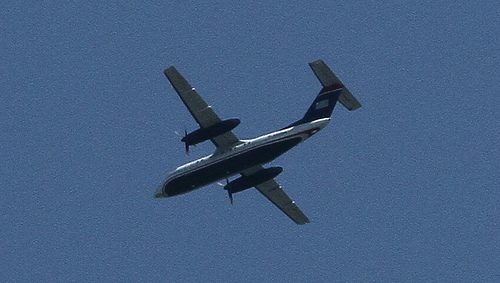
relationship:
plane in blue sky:
[150, 58, 363, 226] [2, 2, 499, 280]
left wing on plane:
[161, 65, 241, 149] [150, 58, 363, 226]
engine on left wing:
[176, 112, 242, 153] [161, 65, 241, 149]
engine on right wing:
[219, 164, 289, 204] [240, 163, 316, 224]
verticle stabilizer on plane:
[304, 60, 362, 122] [150, 58, 363, 226]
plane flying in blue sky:
[150, 58, 363, 226] [2, 2, 499, 280]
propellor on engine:
[173, 127, 199, 154] [176, 112, 242, 153]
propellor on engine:
[216, 174, 236, 206] [219, 164, 289, 204]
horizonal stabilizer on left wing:
[186, 83, 214, 111] [161, 65, 241, 149]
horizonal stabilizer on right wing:
[272, 182, 298, 207] [240, 163, 316, 224]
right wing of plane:
[240, 163, 316, 224] [150, 58, 363, 226]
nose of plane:
[151, 168, 176, 201] [150, 58, 363, 226]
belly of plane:
[165, 135, 307, 196] [150, 58, 363, 226]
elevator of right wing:
[272, 182, 298, 207] [240, 163, 316, 224]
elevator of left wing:
[186, 83, 214, 111] [161, 65, 241, 149]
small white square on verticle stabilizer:
[315, 98, 331, 111] [304, 58, 362, 122]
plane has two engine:
[150, 58, 363, 226] [218, 166, 285, 204]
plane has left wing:
[150, 58, 363, 226] [161, 65, 241, 149]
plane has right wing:
[150, 58, 363, 226] [240, 163, 316, 224]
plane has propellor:
[150, 58, 363, 226] [216, 174, 236, 206]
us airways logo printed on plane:
[315, 98, 331, 111] [150, 58, 363, 226]